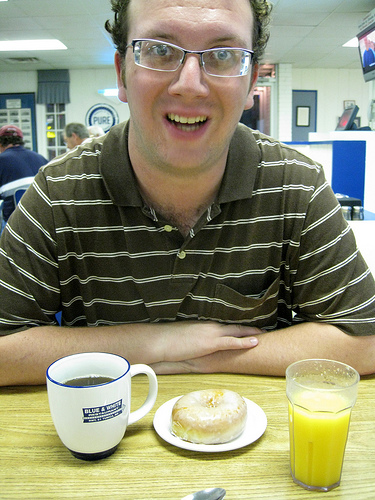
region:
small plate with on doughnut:
[152, 388, 267, 454]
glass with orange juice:
[282, 357, 361, 494]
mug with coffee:
[44, 351, 158, 458]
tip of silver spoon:
[178, 486, 228, 498]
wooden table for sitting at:
[1, 459, 178, 498]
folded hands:
[148, 316, 265, 370]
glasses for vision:
[129, 38, 254, 78]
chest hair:
[154, 202, 196, 227]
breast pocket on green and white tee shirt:
[211, 269, 289, 322]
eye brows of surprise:
[141, 31, 246, 46]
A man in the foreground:
[1, 1, 373, 395]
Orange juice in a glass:
[273, 346, 363, 498]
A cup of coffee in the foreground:
[24, 343, 161, 466]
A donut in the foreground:
[149, 384, 271, 464]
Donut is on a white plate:
[145, 382, 273, 474]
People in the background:
[0, 115, 95, 224]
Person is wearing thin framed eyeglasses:
[118, 33, 258, 87]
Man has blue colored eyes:
[121, 31, 254, 81]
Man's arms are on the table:
[0, 305, 373, 498]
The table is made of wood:
[1, 367, 373, 498]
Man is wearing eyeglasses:
[113, 31, 266, 101]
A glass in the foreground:
[274, 353, 361, 493]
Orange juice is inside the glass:
[271, 350, 362, 493]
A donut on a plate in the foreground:
[147, 381, 271, 456]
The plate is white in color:
[147, 383, 274, 455]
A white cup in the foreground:
[39, 344, 163, 467]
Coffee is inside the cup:
[42, 340, 162, 471]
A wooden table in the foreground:
[1, 364, 373, 495]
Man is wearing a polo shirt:
[1, 109, 373, 377]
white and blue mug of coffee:
[40, 350, 158, 463]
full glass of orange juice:
[284, 354, 360, 493]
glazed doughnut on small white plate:
[150, 385, 269, 460]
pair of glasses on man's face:
[122, 37, 260, 78]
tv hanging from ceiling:
[354, 7, 373, 82]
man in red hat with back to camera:
[0, 124, 51, 216]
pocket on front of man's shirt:
[207, 272, 283, 324]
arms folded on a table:
[0, 307, 371, 385]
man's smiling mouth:
[159, 104, 213, 142]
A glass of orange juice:
[282, 354, 364, 494]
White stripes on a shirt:
[1, 114, 372, 337]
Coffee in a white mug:
[42, 346, 157, 460]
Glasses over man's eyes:
[117, 32, 261, 80]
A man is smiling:
[104, 1, 271, 173]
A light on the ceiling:
[0, 36, 69, 52]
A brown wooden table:
[2, 375, 372, 498]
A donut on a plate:
[151, 384, 269, 456]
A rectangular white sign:
[294, 104, 312, 129]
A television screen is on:
[357, 21, 373, 74]